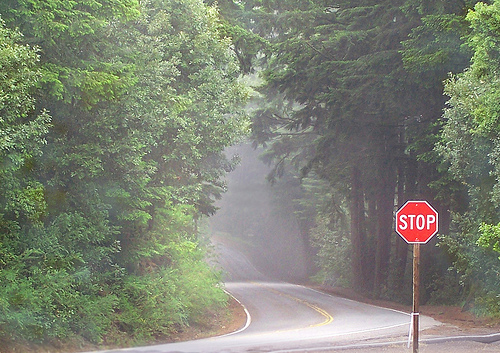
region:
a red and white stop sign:
[393, 196, 440, 244]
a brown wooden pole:
[408, 241, 421, 351]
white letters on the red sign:
[398, 212, 436, 231]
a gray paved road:
[77, 239, 444, 351]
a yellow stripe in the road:
[196, 250, 340, 352]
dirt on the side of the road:
[40, 282, 248, 351]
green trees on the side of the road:
[1, 2, 263, 352]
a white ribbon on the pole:
[403, 308, 418, 350]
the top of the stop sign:
[392, 195, 440, 215]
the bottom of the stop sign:
[396, 230, 441, 241]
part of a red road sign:
[387, 198, 434, 250]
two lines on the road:
[306, 285, 332, 330]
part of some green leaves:
[101, 92, 180, 214]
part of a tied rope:
[404, 310, 415, 320]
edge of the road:
[237, 306, 256, 322]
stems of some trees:
[341, 228, 393, 300]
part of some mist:
[253, 202, 273, 227]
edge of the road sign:
[401, 237, 423, 247]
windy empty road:
[37, 23, 442, 347]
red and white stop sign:
[388, 186, 461, 346]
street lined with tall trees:
[168, 50, 427, 333]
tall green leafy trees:
[313, 1, 450, 283]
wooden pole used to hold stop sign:
[407, 224, 441, 350]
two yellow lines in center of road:
[264, 245, 341, 344]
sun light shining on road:
[207, 303, 434, 349]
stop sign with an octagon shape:
[374, 178, 468, 261]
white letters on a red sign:
[382, 176, 461, 260]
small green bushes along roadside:
[25, 253, 245, 345]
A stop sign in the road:
[391, 197, 446, 351]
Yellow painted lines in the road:
[256, 271, 342, 328]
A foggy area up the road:
[225, 162, 278, 267]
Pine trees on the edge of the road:
[261, 0, 396, 303]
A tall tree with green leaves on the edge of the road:
[438, 5, 498, 328]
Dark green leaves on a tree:
[36, 55, 145, 113]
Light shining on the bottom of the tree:
[156, 199, 233, 326]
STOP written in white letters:
[400, 213, 435, 236]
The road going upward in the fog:
[207, 214, 294, 290]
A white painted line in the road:
[431, 326, 498, 347]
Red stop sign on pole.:
[397, 177, 492, 282]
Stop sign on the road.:
[388, 185, 464, 352]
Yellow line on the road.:
[261, 282, 359, 339]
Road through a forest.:
[194, 242, 386, 351]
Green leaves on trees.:
[250, 9, 414, 241]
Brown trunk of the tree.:
[334, 169, 410, 291]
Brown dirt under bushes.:
[77, 317, 165, 342]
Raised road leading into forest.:
[212, 214, 338, 317]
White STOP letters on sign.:
[385, 190, 451, 261]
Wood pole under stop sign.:
[397, 248, 442, 341]